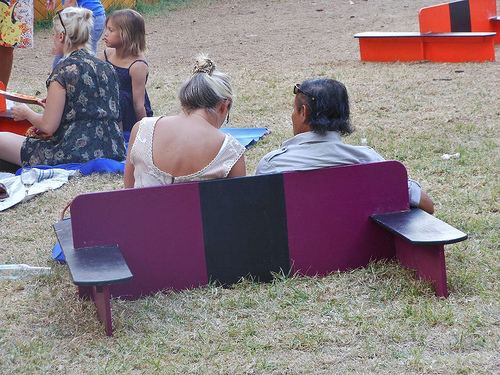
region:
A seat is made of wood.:
[58, 181, 465, 331]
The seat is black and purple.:
[48, 168, 469, 323]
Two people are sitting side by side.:
[118, 49, 440, 240]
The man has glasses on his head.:
[279, 75, 366, 149]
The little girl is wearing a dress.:
[88, 1, 157, 126]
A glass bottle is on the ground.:
[5, 255, 54, 286]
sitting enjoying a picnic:
[256, 77, 433, 216]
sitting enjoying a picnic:
[121, 53, 251, 193]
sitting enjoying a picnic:
[0, 8, 129, 169]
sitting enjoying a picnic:
[100, 7, 155, 129]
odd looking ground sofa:
[49, 161, 465, 335]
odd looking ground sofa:
[350, 1, 497, 61]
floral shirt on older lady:
[19, 48, 125, 163]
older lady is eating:
[0, 5, 126, 169]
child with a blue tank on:
[96, 6, 153, 124]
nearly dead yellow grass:
[0, 3, 497, 371]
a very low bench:
[50, 153, 465, 339]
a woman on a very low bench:
[54, 52, 469, 343]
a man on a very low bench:
[41, 49, 485, 339]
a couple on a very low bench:
[48, 56, 487, 346]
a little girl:
[97, 6, 192, 133]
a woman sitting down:
[8, 5, 131, 170]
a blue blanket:
[8, 143, 122, 185]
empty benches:
[336, 0, 488, 67]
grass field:
[159, 8, 339, 55]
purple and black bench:
[66, 182, 491, 269]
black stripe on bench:
[173, 188, 298, 288]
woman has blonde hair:
[164, 73, 229, 110]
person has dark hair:
[291, 58, 359, 166]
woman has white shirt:
[133, 99, 225, 211]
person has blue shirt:
[256, 132, 378, 208]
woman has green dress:
[23, 48, 150, 193]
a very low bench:
[36, 157, 473, 336]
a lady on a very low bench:
[48, 49, 484, 339]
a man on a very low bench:
[54, 54, 483, 343]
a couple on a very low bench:
[45, 52, 482, 345]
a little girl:
[86, 8, 187, 149]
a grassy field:
[154, 11, 346, 73]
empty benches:
[346, 5, 497, 75]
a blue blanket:
[17, 156, 122, 177]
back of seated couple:
[124, 56, 434, 213]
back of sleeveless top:
[124, 114, 247, 184]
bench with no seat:
[58, 159, 465, 336]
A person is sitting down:
[123, 62, 243, 222]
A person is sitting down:
[263, 75, 435, 233]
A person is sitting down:
[98, 11, 179, 135]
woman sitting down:
[125, 57, 250, 178]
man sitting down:
[255, 70, 436, 216]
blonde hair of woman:
[165, 52, 226, 102]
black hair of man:
[296, 77, 357, 127]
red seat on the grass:
[345, 1, 495, 57]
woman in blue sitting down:
[7, 7, 122, 177]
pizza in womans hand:
[5, 82, 45, 103]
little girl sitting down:
[87, 20, 152, 110]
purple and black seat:
[56, 151, 458, 306]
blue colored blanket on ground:
[55, 125, 270, 178]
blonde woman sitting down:
[126, 53, 246, 181]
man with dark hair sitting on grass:
[240, 77, 448, 217]